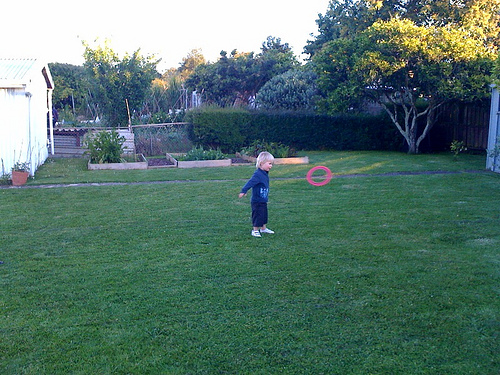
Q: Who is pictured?
A: A little boy.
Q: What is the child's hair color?
A: Blonde.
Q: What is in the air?
A: A disk.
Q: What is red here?
A: Frisbee.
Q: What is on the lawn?
A: A garden.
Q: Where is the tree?
A: In the corner.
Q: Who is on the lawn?
A: A boy.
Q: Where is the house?
A: On the left.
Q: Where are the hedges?
A: By the tree.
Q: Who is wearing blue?
A: The boy.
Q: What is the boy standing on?
A: Grass.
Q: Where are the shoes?
A: Boys feet.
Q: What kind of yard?
A: Backyard.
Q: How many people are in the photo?
A: One.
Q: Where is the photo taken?
A: Outside in a yard.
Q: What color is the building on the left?
A: White.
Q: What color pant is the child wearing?
A: Blue.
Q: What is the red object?
A: A flying ring.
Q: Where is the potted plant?
A: Next to the white building.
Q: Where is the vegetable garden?
A: In the background to the right of the white building.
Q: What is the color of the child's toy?
A: Red.